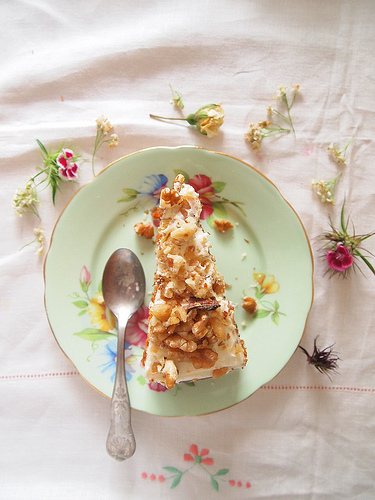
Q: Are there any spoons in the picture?
A: Yes, there is a spoon.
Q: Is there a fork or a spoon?
A: Yes, there is a spoon.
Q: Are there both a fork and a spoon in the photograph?
A: No, there is a spoon but no forks.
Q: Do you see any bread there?
A: No, there is no breads.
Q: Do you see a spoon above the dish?
A: Yes, there is a spoon above the dish.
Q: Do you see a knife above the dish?
A: No, there is a spoon above the dish.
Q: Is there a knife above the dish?
A: No, there is a spoon above the dish.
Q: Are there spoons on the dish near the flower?
A: Yes, there is a spoon on the dish.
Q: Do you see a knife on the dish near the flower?
A: No, there is a spoon on the dish.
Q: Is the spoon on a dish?
A: Yes, the spoon is on a dish.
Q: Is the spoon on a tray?
A: No, the spoon is on a dish.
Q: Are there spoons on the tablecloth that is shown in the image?
A: Yes, there is a spoon on the tablecloth.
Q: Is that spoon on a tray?
A: No, the spoon is on a tablecloth.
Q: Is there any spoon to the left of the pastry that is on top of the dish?
A: Yes, there is a spoon to the left of the pastry.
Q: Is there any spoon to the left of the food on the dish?
A: Yes, there is a spoon to the left of the pastry.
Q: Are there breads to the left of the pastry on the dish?
A: No, there is a spoon to the left of the pastry.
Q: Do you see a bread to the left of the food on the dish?
A: No, there is a spoon to the left of the pastry.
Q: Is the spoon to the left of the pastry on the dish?
A: Yes, the spoon is to the left of the pastry.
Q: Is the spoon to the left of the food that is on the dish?
A: Yes, the spoon is to the left of the pastry.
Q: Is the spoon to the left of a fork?
A: No, the spoon is to the left of the pastry.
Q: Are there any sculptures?
A: No, there are no sculptures.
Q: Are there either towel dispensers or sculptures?
A: No, there are no sculptures or towel dispensers.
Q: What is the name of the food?
A: The food is a pastry.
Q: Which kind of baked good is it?
A: The food is a pastry.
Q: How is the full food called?
A: The food is a pastry.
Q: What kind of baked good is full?
A: The baked good is a pastry.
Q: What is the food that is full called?
A: The food is a pastry.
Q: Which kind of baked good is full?
A: The baked good is a pastry.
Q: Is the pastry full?
A: Yes, the pastry is full.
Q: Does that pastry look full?
A: Yes, the pastry is full.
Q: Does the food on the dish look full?
A: Yes, the pastry is full.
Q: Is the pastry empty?
A: No, the pastry is full.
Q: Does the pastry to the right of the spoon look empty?
A: No, the pastry is full.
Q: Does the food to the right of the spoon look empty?
A: No, the pastry is full.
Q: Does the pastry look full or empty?
A: The pastry is full.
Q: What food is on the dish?
A: The food is a pastry.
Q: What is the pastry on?
A: The pastry is on the dish.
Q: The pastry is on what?
A: The pastry is on the dish.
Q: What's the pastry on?
A: The pastry is on the dish.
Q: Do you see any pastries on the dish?
A: Yes, there is a pastry on the dish.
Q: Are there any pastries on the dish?
A: Yes, there is a pastry on the dish.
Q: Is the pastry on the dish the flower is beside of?
A: Yes, the pastry is on the dish.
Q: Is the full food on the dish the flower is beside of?
A: Yes, the pastry is on the dish.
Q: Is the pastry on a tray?
A: No, the pastry is on the dish.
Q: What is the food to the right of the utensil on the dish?
A: The food is a pastry.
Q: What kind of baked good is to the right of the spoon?
A: The food is a pastry.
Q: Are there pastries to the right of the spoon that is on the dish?
A: Yes, there is a pastry to the right of the spoon.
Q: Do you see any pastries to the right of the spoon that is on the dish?
A: Yes, there is a pastry to the right of the spoon.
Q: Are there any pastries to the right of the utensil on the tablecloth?
A: Yes, there is a pastry to the right of the spoon.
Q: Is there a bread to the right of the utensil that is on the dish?
A: No, there is a pastry to the right of the spoon.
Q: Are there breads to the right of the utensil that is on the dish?
A: No, there is a pastry to the right of the spoon.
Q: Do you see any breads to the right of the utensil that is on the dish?
A: No, there is a pastry to the right of the spoon.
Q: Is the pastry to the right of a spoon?
A: Yes, the pastry is to the right of a spoon.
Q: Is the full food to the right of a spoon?
A: Yes, the pastry is to the right of a spoon.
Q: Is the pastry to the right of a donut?
A: No, the pastry is to the right of a spoon.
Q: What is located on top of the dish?
A: The pastry is on top of the dish.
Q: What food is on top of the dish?
A: The food is a pastry.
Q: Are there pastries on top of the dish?
A: Yes, there is a pastry on top of the dish.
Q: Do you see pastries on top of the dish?
A: Yes, there is a pastry on top of the dish.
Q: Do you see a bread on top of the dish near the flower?
A: No, there is a pastry on top of the dish.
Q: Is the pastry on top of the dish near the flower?
A: Yes, the pastry is on top of the dish.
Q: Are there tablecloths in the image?
A: Yes, there is a tablecloth.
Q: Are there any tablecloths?
A: Yes, there is a tablecloth.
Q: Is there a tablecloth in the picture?
A: Yes, there is a tablecloth.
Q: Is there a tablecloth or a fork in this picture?
A: Yes, there is a tablecloth.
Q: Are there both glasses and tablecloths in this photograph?
A: No, there is a tablecloth but no glasses.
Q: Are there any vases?
A: No, there are no vases.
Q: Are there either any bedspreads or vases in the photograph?
A: No, there are no vases or bedspreads.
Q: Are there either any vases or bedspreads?
A: No, there are no vases or bedspreads.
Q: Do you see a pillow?
A: No, there are no pillows.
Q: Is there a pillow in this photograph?
A: No, there are no pillows.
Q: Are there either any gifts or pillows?
A: No, there are no pillows or gifts.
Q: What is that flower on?
A: The flower is on the tablecloth.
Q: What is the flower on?
A: The flower is on the tablecloth.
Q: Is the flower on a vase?
A: No, the flower is on a tablecloth.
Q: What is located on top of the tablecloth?
A: The flower is on top of the tablecloth.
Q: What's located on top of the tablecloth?
A: The flower is on top of the tablecloth.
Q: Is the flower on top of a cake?
A: No, the flower is on top of a tablecloth.